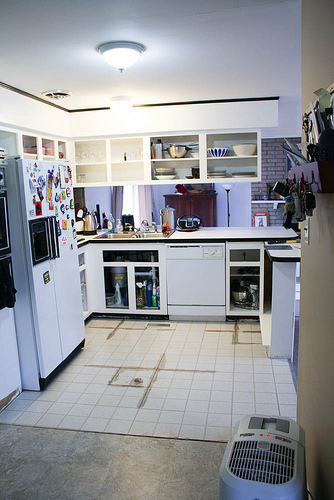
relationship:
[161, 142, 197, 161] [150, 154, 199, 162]
bowl on shelf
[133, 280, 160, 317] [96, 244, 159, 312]
cleaning products in cabinet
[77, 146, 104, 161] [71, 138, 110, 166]
wine glasses on shelf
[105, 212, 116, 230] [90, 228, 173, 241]
detergent near sink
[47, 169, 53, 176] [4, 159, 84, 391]
clip on fridge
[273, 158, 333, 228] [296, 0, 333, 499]
rack hangs on wall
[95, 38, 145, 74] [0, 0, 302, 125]
light hangs on ceiling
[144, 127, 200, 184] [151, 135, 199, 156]
cabinet contains appliances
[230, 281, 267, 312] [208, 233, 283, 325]
mixer in cabinet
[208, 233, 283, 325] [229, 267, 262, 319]
cabinet has shelf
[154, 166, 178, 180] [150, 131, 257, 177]
dishes stacked in cabinets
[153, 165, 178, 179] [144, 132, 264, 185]
dishes in cabinet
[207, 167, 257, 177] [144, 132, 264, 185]
dishes in cabinet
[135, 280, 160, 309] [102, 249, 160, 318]
cleaning products in cabinet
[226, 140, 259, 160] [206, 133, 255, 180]
bowl in a cabinet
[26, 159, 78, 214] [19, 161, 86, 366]
magnets on refrigerator door